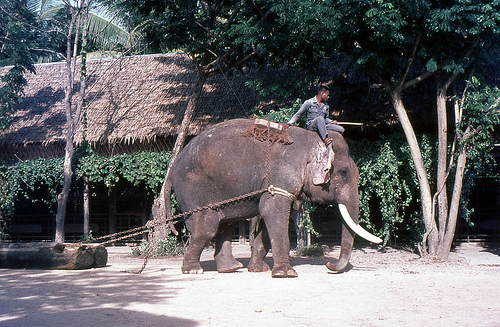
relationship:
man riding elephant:
[288, 82, 349, 148] [156, 110, 387, 282]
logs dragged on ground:
[0, 241, 114, 269] [3, 237, 497, 321]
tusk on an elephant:
[327, 203, 390, 249] [141, 97, 372, 257]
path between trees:
[457, 224, 493, 277] [220, 0, 492, 266]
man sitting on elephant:
[288, 82, 349, 148] [156, 110, 387, 282]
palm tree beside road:
[36, 0, 102, 248] [2, 265, 499, 325]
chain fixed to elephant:
[63, 181, 297, 246] [159, 93, 366, 283]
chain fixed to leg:
[63, 181, 297, 246] [256, 180, 298, 285]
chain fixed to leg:
[63, 181, 297, 246] [167, 200, 231, 279]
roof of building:
[82, 62, 189, 134] [4, 55, 194, 240]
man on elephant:
[288, 82, 349, 148] [184, 117, 374, 258]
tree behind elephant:
[353, 5, 494, 264] [166, 117, 383, 279]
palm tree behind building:
[18, 2, 154, 53] [0, 52, 336, 239]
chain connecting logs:
[63, 181, 290, 248] [3, 229, 125, 273]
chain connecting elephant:
[63, 181, 290, 248] [137, 109, 391, 284]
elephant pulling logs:
[160, 117, 384, 279] [0, 232, 125, 276]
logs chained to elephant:
[0, 241, 100, 269] [156, 110, 387, 282]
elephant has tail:
[160, 117, 384, 279] [143, 167, 195, 249]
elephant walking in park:
[166, 117, 383, 279] [6, 4, 491, 317]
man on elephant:
[303, 82, 333, 135] [168, 122, 378, 247]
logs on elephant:
[0, 241, 114, 269] [137, 109, 391, 284]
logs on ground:
[0, 241, 114, 269] [2, 225, 494, 320]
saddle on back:
[245, 115, 291, 144] [176, 120, 319, 154]